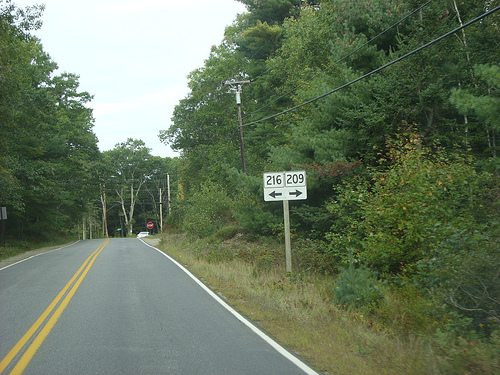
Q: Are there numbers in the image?
A: Yes, there are numbers.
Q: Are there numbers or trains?
A: Yes, there are numbers.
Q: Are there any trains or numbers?
A: Yes, there are numbers.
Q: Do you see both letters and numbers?
A: No, there are numbers but no letters.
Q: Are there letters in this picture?
A: No, there are no letters.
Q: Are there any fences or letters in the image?
A: No, there are no letters or fences.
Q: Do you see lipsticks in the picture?
A: No, there are no lipsticks.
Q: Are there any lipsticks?
A: No, there are no lipsticks.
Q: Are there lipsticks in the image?
A: No, there are no lipsticks.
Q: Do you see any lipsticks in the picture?
A: No, there are no lipsticks.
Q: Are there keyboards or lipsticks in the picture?
A: No, there are no lipsticks or keyboards.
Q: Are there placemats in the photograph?
A: No, there are no placemats.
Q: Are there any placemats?
A: No, there are no placemats.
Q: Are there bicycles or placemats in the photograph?
A: No, there are no placemats or bicycles.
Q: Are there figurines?
A: No, there are no figurines.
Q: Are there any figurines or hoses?
A: No, there are no figurines or hoses.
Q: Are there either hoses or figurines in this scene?
A: No, there are no figurines or hoses.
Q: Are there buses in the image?
A: No, there are no buses.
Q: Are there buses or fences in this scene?
A: No, there are no buses or fences.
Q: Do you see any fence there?
A: No, there are no fences.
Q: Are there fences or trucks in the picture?
A: No, there are no fences or trucks.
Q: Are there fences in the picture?
A: No, there are no fences.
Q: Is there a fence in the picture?
A: No, there are no fences.